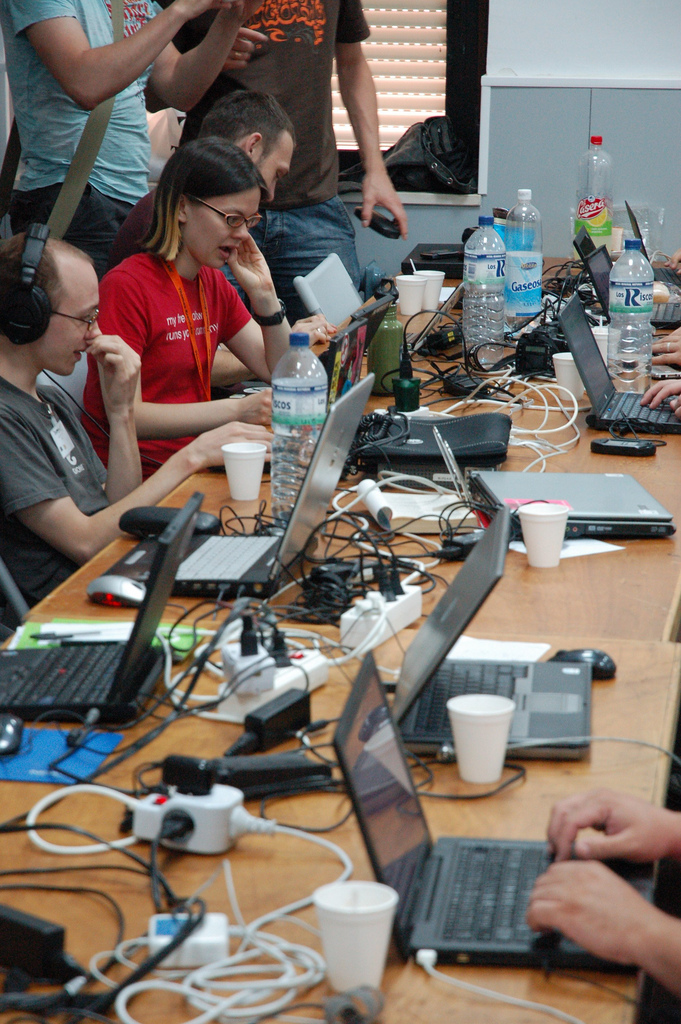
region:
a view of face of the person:
[117, 130, 310, 289]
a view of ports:
[429, 928, 505, 970]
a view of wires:
[471, 959, 567, 1021]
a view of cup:
[291, 861, 422, 1017]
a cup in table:
[282, 845, 405, 1003]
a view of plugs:
[86, 727, 339, 925]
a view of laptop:
[296, 676, 503, 903]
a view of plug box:
[189, 613, 365, 728]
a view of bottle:
[251, 297, 343, 522]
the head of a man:
[3, 223, 104, 390]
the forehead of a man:
[50, 246, 104, 314]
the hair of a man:
[33, 256, 62, 296]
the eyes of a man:
[75, 308, 102, 335]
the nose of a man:
[81, 318, 110, 345]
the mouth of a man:
[62, 343, 95, 362]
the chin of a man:
[35, 355, 87, 388]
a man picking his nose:
[3, 219, 183, 545]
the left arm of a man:
[87, 322, 160, 493]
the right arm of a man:
[5, 409, 292, 545]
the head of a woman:
[147, 133, 316, 284]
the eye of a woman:
[198, 203, 246, 239]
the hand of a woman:
[215, 213, 306, 298]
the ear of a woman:
[169, 186, 207, 240]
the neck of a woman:
[134, 217, 205, 298]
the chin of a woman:
[192, 238, 244, 290]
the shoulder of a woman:
[81, 236, 156, 323]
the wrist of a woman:
[219, 256, 343, 333]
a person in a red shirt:
[107, 136, 266, 416]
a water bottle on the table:
[469, 217, 507, 342]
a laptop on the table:
[322, 654, 637, 971]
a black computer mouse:
[552, 643, 614, 677]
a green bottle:
[374, 279, 407, 379]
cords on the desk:
[126, 876, 316, 1007]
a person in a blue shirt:
[1, 11, 157, 197]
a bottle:
[580, 137, 604, 231]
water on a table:
[608, 227, 673, 367]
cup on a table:
[315, 874, 398, 995]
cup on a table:
[438, 685, 534, 786]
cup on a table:
[512, 495, 574, 578]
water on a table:
[445, 205, 502, 352]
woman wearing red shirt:
[143, 134, 285, 390]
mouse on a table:
[75, 570, 152, 606]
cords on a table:
[308, 513, 358, 601]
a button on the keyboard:
[467, 884, 496, 907]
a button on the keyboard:
[485, 885, 508, 917]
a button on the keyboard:
[503, 900, 514, 923]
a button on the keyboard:
[441, 900, 471, 926]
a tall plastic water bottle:
[465, 216, 510, 339]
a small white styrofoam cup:
[311, 878, 400, 998]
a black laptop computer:
[385, 503, 603, 755]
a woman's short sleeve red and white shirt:
[80, 250, 252, 483]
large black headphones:
[0, 224, 63, 355]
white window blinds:
[317, 0, 444, 157]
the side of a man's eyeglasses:
[47, 307, 106, 334]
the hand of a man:
[359, 157, 408, 237]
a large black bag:
[351, 113, 475, 199]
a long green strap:
[0, 0, 133, 247]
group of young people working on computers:
[2, 85, 679, 1007]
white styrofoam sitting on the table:
[448, 692, 516, 785]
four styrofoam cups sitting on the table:
[220, 441, 566, 1001]